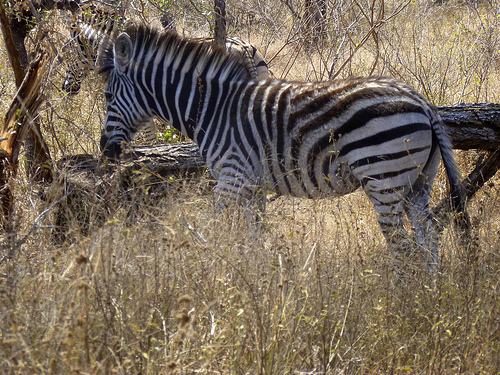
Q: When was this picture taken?
A: Daytime.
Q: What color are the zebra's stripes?
A: Black.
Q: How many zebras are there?
A: Two.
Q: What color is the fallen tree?
A: Brown.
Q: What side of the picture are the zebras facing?
A: Left.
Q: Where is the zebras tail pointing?
A: Down.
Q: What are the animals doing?
A: Standing.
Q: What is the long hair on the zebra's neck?
A: Its mane.